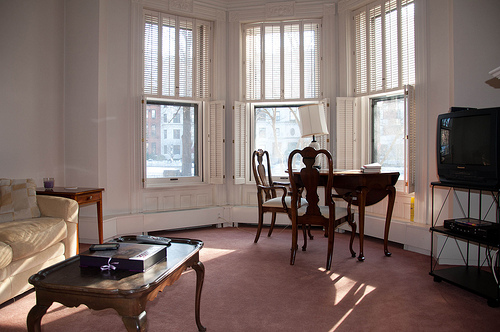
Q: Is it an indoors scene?
A: Yes, it is indoors.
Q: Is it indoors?
A: Yes, it is indoors.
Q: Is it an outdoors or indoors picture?
A: It is indoors.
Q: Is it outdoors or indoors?
A: It is indoors.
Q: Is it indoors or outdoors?
A: It is indoors.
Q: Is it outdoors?
A: No, it is indoors.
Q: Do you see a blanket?
A: No, there are no blankets.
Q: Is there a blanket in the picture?
A: No, there are no blankets.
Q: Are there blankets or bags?
A: No, there are no blankets or bags.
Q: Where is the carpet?
A: The carpet is on the floor.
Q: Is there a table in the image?
A: Yes, there is a table.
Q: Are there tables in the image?
A: Yes, there is a table.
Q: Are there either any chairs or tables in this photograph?
A: Yes, there is a table.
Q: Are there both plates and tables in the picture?
A: No, there is a table but no plates.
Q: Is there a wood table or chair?
A: Yes, there is a wood table.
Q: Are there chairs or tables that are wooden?
A: Yes, the table is wooden.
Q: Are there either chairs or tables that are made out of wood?
A: Yes, the table is made of wood.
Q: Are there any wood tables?
A: Yes, there is a wood table.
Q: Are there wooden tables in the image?
A: Yes, there is a wood table.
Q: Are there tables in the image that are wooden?
A: Yes, there is a table that is wooden.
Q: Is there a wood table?
A: Yes, there is a table that is made of wood.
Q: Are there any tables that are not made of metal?
A: Yes, there is a table that is made of wood.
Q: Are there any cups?
A: No, there are no cups.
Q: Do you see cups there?
A: No, there are no cups.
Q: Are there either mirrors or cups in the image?
A: No, there are no cups or mirrors.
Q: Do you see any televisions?
A: Yes, there is a television.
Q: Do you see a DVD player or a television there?
A: Yes, there is a television.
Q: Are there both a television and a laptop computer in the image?
A: No, there is a television but no laptops.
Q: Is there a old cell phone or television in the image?
A: Yes, there is an old television.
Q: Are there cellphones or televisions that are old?
A: Yes, the television is old.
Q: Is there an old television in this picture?
A: Yes, there is an old television.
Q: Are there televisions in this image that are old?
A: Yes, there is a television that is old.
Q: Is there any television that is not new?
A: Yes, there is a old television.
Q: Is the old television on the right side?
A: Yes, the TV is on the right of the image.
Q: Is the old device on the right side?
A: Yes, the TV is on the right of the image.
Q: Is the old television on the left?
A: No, the TV is on the right of the image.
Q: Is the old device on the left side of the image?
A: No, the TV is on the right of the image.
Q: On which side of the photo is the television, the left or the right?
A: The television is on the right of the image.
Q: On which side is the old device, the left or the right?
A: The television is on the right of the image.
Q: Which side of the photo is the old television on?
A: The TV is on the right of the image.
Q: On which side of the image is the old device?
A: The TV is on the right of the image.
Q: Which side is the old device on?
A: The TV is on the right of the image.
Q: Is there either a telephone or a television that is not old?
A: No, there is a television but it is old.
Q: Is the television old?
A: Yes, the television is old.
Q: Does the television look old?
A: Yes, the television is old.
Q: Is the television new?
A: No, the television is old.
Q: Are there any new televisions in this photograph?
A: No, there is a television but it is old.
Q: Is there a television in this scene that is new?
A: No, there is a television but it is old.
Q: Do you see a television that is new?
A: No, there is a television but it is old.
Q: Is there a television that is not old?
A: No, there is a television but it is old.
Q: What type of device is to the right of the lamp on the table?
A: The device is a television.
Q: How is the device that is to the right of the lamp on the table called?
A: The device is a television.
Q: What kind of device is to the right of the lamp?
A: The device is a television.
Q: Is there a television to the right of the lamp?
A: Yes, there is a television to the right of the lamp.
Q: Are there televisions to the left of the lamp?
A: No, the television is to the right of the lamp.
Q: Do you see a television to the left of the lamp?
A: No, the television is to the right of the lamp.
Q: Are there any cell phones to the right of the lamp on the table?
A: No, there is a television to the right of the lamp.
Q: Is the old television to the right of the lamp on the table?
A: Yes, the television is to the right of the lamp.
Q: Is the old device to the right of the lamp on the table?
A: Yes, the television is to the right of the lamp.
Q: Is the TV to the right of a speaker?
A: No, the TV is to the right of the lamp.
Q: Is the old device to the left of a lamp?
A: No, the television is to the right of a lamp.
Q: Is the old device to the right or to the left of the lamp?
A: The television is to the right of the lamp.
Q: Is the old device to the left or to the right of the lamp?
A: The television is to the right of the lamp.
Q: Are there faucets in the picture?
A: No, there are no faucets.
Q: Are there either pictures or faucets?
A: No, there are no faucets or pictures.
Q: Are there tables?
A: Yes, there is a table.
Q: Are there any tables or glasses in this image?
A: Yes, there is a table.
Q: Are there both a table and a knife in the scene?
A: No, there is a table but no knives.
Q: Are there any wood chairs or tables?
A: Yes, there is a wood table.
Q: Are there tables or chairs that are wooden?
A: Yes, the table is wooden.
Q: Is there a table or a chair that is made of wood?
A: Yes, the table is made of wood.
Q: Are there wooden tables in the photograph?
A: Yes, there is a wood table.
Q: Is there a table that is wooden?
A: Yes, there is a table that is wooden.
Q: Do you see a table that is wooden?
A: Yes, there is a table that is wooden.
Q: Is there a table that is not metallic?
A: Yes, there is a wooden table.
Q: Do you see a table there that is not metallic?
A: Yes, there is a wooden table.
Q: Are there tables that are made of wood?
A: Yes, there is a table that is made of wood.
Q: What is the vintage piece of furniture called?
A: The piece of furniture is a table.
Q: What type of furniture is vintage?
A: The furniture is a table.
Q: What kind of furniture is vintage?
A: The furniture is a table.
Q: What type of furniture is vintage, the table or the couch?
A: The table is vintage.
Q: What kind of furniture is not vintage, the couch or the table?
A: The couch is not vintage.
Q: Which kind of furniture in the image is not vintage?
A: The furniture is a couch.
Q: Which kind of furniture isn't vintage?
A: The furniture is a couch.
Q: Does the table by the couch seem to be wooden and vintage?
A: Yes, the table is wooden and vintage.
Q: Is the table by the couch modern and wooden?
A: No, the table is wooden but vintage.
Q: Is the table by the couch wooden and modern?
A: No, the table is wooden but vintage.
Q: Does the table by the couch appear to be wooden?
A: Yes, the table is wooden.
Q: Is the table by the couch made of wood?
A: Yes, the table is made of wood.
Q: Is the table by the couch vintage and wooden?
A: Yes, the table is vintage and wooden.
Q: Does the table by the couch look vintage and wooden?
A: Yes, the table is vintage and wooden.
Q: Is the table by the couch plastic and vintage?
A: No, the table is vintage but wooden.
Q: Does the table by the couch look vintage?
A: Yes, the table is vintage.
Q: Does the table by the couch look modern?
A: No, the table is vintage.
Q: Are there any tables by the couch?
A: Yes, there is a table by the couch.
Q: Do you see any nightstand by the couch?
A: No, there is a table by the couch.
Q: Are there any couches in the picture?
A: Yes, there is a couch.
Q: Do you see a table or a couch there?
A: Yes, there is a couch.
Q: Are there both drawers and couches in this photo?
A: Yes, there are both a couch and a drawer.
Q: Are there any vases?
A: No, there are no vases.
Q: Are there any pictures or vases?
A: No, there are no vases or pictures.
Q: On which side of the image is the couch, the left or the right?
A: The couch is on the left of the image.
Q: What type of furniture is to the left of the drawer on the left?
A: The piece of furniture is a couch.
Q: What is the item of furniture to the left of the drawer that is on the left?
A: The piece of furniture is a couch.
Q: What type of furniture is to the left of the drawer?
A: The piece of furniture is a couch.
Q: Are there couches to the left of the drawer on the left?
A: Yes, there is a couch to the left of the drawer.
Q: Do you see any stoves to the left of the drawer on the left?
A: No, there is a couch to the left of the drawer.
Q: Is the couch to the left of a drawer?
A: Yes, the couch is to the left of a drawer.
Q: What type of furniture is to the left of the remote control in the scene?
A: The piece of furniture is a couch.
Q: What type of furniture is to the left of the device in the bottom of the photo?
A: The piece of furniture is a couch.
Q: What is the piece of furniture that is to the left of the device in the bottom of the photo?
A: The piece of furniture is a couch.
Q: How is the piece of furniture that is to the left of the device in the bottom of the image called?
A: The piece of furniture is a couch.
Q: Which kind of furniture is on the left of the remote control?
A: The piece of furniture is a couch.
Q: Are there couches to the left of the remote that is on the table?
A: Yes, there is a couch to the left of the remote control.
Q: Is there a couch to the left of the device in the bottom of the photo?
A: Yes, there is a couch to the left of the remote control.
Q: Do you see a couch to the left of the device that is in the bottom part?
A: Yes, there is a couch to the left of the remote control.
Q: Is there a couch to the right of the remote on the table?
A: No, the couch is to the left of the remote.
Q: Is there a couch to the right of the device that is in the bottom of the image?
A: No, the couch is to the left of the remote.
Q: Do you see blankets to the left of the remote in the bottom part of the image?
A: No, there is a couch to the left of the remote control.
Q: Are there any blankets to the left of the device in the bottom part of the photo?
A: No, there is a couch to the left of the remote control.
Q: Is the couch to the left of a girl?
A: No, the couch is to the left of the remote control.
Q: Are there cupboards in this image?
A: No, there are no cupboards.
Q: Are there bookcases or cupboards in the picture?
A: No, there are no cupboards or bookcases.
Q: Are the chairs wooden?
A: Yes, the chairs are wooden.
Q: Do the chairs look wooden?
A: Yes, the chairs are wooden.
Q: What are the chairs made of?
A: The chairs are made of wood.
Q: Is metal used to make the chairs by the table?
A: No, the chairs are made of wood.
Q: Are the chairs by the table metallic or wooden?
A: The chairs are wooden.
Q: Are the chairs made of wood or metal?
A: The chairs are made of wood.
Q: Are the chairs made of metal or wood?
A: The chairs are made of wood.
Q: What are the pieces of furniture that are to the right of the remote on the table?
A: The pieces of furniture are chairs.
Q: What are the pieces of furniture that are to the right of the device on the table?
A: The pieces of furniture are chairs.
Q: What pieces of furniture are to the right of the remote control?
A: The pieces of furniture are chairs.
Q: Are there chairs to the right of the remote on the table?
A: Yes, there are chairs to the right of the remote control.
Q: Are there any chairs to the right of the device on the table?
A: Yes, there are chairs to the right of the remote control.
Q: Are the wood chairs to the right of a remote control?
A: Yes, the chairs are to the right of a remote control.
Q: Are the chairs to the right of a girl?
A: No, the chairs are to the right of a remote control.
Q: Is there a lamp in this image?
A: Yes, there is a lamp.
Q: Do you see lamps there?
A: Yes, there is a lamp.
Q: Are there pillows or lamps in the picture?
A: Yes, there is a lamp.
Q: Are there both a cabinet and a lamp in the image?
A: No, there is a lamp but no cabinets.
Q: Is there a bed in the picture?
A: No, there are no beds.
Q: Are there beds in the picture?
A: No, there are no beds.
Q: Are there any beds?
A: No, there are no beds.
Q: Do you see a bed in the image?
A: No, there are no beds.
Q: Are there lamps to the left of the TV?
A: Yes, there is a lamp to the left of the TV.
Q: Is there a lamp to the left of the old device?
A: Yes, there is a lamp to the left of the TV.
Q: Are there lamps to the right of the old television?
A: No, the lamp is to the left of the TV.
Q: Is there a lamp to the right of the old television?
A: No, the lamp is to the left of the TV.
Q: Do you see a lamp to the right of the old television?
A: No, the lamp is to the left of the TV.